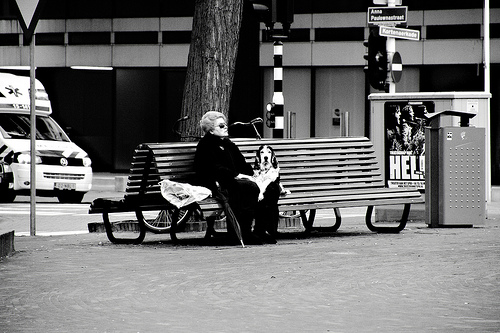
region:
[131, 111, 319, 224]
A bicycle leaning against a tree.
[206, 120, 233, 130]
A dark colored pair of glasses.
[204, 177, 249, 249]
An umbrella.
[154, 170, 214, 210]
A white plastic bag.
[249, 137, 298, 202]
A dog.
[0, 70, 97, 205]
A hospital van.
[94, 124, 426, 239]
A long bench.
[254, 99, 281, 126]
A traffic light.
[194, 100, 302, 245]
A woman and her dog sitting on a bench.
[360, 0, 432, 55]
Street signs on a pole.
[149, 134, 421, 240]
a wood slat bench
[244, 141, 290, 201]
a dog sitting on bench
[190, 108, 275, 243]
a woman sitting on bench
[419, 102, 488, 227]
a large trash can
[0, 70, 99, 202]
a white ambulance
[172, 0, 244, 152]
a tall tree truck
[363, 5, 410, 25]
a street name sign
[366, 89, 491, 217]
a telephone service box with poster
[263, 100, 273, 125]
an electric traffic signal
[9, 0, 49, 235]
a traffic street sign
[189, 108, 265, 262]
a woman in black sitting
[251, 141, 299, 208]
a sog sitting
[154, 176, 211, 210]
a white bag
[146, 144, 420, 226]
a long public bench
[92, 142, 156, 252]
part of a bench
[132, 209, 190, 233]
part of a bicycle wheel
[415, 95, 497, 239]
a trash can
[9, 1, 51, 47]
part of a street sign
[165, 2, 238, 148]
part of a tree trunk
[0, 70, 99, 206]
part of an ambulance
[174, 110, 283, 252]
a woman sitting on a bench.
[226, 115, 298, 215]
a dog sitting on a bench.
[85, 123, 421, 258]
a wooden bench near a tree.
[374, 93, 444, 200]
a poster that says help.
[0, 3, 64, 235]
a road sign.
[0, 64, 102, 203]
a parked ambulance.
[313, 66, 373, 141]
a large window.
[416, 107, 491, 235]
a trash can.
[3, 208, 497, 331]
a paved waiting area.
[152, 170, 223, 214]
a bag on a bench.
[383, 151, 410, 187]
the white letter h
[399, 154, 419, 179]
the white letter e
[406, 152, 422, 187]
the white letter l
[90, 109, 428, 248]
this is a bench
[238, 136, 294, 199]
this is a dog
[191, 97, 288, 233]
this is a woman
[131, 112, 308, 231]
this is a bike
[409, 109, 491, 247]
this is a trashcan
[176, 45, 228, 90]
this is tree bark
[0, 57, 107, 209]
this is a truck